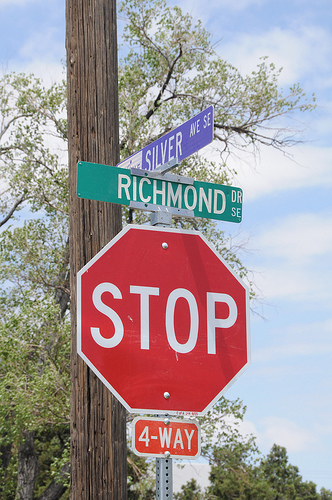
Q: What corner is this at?
A: Richmond and Silver.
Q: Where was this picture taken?
A: Street corner.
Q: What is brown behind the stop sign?
A: Pole.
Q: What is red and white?
A: Stop sign.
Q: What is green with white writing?
A: Street sign.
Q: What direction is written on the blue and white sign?
A: Southeast.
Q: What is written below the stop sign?
A: 4-way.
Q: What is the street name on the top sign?
A: Silver Ave SE.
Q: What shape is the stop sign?
A: Octagon.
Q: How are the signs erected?
A: On a pole.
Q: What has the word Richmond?
A: Green street sign.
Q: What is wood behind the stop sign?
A: Telephone pole.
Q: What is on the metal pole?
A: Signs.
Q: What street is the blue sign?
A: Silver.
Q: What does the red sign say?
A: STOP.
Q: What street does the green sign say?
A: Richmond.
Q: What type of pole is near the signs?
A: Wood.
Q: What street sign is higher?
A: Silver.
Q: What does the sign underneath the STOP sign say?
A: 4 way.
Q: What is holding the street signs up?
A: Metal pole.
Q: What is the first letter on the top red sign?
A: S.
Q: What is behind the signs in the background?
A: Trees.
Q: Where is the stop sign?
A: On the street.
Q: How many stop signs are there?
A: One.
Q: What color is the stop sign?
A: Red.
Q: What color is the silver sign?
A: Blue.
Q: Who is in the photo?
A: No one.